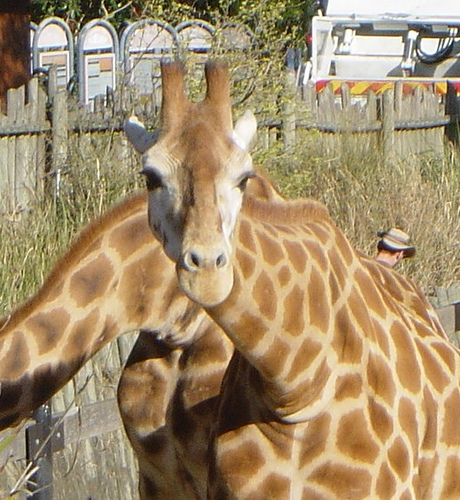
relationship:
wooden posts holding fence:
[34, 65, 89, 191] [1, 76, 457, 214]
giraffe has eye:
[109, 47, 457, 498] [231, 174, 255, 193]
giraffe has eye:
[109, 47, 457, 498] [142, 162, 166, 194]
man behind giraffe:
[372, 224, 417, 270] [109, 47, 457, 498]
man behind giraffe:
[372, 224, 417, 270] [0, 164, 304, 496]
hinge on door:
[25, 421, 49, 458] [0, 409, 138, 497]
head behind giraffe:
[378, 227, 414, 266] [109, 47, 457, 498]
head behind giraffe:
[378, 227, 414, 266] [0, 186, 237, 497]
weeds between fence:
[22, 145, 451, 317] [1, 76, 457, 214]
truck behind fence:
[295, 1, 459, 105] [0, 57, 458, 225]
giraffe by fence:
[109, 47, 457, 498] [0, 57, 458, 225]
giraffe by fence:
[0, 59, 458, 498] [1, 76, 457, 214]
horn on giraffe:
[159, 60, 188, 121] [109, 47, 457, 498]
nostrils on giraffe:
[182, 251, 229, 271] [109, 47, 457, 498]